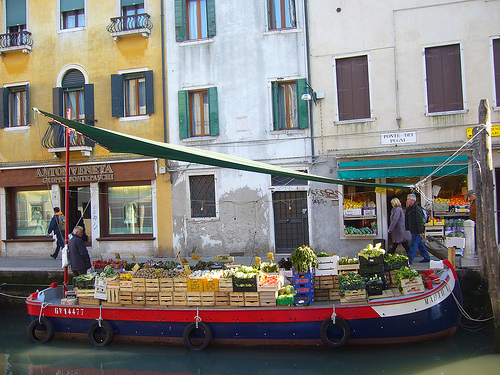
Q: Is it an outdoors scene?
A: Yes, it is outdoors.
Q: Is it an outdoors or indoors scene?
A: It is outdoors.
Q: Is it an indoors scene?
A: No, it is outdoors.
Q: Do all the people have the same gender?
A: No, they are both male and female.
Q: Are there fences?
A: No, there are no fences.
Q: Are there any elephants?
A: No, there are no elephants.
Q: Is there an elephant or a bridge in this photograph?
A: No, there are no elephants or bridges.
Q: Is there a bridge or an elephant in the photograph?
A: No, there are no elephants or bridges.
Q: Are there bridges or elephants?
A: No, there are no elephants or bridges.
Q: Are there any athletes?
A: No, there are no athletes.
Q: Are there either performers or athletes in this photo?
A: No, there are no athletes or performers.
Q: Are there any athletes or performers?
A: No, there are no athletes or performers.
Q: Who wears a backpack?
A: The man wears a backpack.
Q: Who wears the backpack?
A: The man wears a backpack.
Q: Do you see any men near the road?
A: Yes, there is a man near the road.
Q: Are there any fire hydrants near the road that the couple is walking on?
A: No, there is a man near the road.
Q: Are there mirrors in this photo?
A: No, there are no mirrors.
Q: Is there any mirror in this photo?
A: No, there are no mirrors.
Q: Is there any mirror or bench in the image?
A: No, there are no mirrors or benches.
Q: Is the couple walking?
A: Yes, the couple is walking.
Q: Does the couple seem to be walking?
A: Yes, the couple is walking.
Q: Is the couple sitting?
A: No, the couple is walking.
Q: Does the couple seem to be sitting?
A: No, the couple is walking.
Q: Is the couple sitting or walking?
A: The couple is walking.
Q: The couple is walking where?
A: The couple is walking on the road.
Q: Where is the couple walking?
A: The couple is walking on the road.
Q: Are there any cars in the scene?
A: No, there are no cars.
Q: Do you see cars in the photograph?
A: No, there are no cars.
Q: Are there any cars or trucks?
A: No, there are no cars or trucks.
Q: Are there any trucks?
A: No, there are no trucks.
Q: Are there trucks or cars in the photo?
A: No, there are no trucks or cars.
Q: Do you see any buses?
A: No, there are no buses.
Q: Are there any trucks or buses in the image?
A: No, there are no buses or trucks.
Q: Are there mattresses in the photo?
A: No, there are no mattresses.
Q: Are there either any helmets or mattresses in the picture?
A: No, there are no mattresses or helmets.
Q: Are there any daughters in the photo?
A: No, there are no daughters.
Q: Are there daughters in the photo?
A: No, there are no daughters.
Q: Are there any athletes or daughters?
A: No, there are no daughters or athletes.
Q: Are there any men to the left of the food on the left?
A: Yes, there is a man to the left of the food.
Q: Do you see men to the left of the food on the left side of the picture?
A: Yes, there is a man to the left of the food.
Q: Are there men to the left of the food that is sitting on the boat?
A: Yes, there is a man to the left of the food.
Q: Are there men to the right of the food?
A: No, the man is to the left of the food.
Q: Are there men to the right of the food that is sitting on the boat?
A: No, the man is to the left of the food.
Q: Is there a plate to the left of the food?
A: No, there is a man to the left of the food.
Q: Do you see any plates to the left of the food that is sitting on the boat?
A: No, there is a man to the left of the food.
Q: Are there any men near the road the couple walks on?
A: Yes, there is a man near the road.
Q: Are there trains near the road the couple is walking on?
A: No, there is a man near the road.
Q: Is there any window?
A: Yes, there is a window.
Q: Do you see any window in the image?
A: Yes, there is a window.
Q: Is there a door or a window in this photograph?
A: Yes, there is a window.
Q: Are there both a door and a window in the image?
A: Yes, there are both a window and a door.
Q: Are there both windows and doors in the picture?
A: Yes, there are both a window and a door.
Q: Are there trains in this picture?
A: No, there are no trains.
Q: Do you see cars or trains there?
A: No, there are no trains or cars.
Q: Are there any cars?
A: No, there are no cars.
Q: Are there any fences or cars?
A: No, there are no cars or fences.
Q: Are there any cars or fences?
A: No, there are no cars or fences.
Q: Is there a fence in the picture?
A: No, there are no fences.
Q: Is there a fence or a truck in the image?
A: No, there are no fences or trucks.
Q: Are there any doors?
A: Yes, there is a door.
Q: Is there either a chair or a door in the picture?
A: Yes, there is a door.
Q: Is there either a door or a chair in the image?
A: Yes, there is a door.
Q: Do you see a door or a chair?
A: Yes, there is a door.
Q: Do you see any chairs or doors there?
A: Yes, there is a door.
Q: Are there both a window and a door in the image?
A: Yes, there are both a door and a window.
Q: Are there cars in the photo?
A: No, there are no cars.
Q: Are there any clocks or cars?
A: No, there are no cars or clocks.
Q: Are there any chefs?
A: No, there are no chefs.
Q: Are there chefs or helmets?
A: No, there are no chefs or helmets.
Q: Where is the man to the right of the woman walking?
A: The man is walking on the road.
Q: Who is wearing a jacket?
A: The man is wearing a jacket.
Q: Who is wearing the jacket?
A: The man is wearing a jacket.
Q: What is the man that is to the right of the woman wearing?
A: The man is wearing a jacket.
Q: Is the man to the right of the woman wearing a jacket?
A: Yes, the man is wearing a jacket.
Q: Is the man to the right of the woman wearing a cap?
A: No, the man is wearing a jacket.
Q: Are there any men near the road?
A: Yes, there is a man near the road.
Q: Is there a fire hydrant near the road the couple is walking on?
A: No, there is a man near the road.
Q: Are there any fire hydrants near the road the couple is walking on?
A: No, there is a man near the road.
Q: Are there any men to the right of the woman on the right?
A: Yes, there is a man to the right of the woman.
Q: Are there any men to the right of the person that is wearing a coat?
A: Yes, there is a man to the right of the woman.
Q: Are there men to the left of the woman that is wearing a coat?
A: No, the man is to the right of the woman.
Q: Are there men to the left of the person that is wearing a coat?
A: No, the man is to the right of the woman.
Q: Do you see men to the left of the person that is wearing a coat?
A: No, the man is to the right of the woman.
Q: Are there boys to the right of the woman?
A: No, there is a man to the right of the woman.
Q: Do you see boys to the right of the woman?
A: No, there is a man to the right of the woman.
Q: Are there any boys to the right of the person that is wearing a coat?
A: No, there is a man to the right of the woman.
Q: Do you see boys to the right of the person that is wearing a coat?
A: No, there is a man to the right of the woman.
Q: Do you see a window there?
A: Yes, there is a window.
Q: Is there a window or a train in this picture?
A: Yes, there is a window.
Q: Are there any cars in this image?
A: No, there are no cars.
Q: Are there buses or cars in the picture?
A: No, there are no cars or buses.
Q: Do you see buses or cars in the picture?
A: No, there are no cars or buses.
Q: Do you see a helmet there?
A: No, there are no helmets.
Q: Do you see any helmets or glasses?
A: No, there are no helmets or glasses.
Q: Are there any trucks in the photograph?
A: No, there are no trucks.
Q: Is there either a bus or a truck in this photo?
A: No, there are no trucks or buses.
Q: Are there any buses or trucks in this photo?
A: No, there are no trucks or buses.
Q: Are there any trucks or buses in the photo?
A: No, there are no trucks or buses.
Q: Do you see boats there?
A: Yes, there is a boat.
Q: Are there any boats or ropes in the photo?
A: Yes, there is a boat.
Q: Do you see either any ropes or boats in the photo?
A: Yes, there is a boat.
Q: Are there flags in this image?
A: No, there are no flags.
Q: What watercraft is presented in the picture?
A: The watercraft is a boat.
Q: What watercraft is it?
A: The watercraft is a boat.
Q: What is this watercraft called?
A: This is a boat.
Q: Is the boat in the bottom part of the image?
A: Yes, the boat is in the bottom of the image.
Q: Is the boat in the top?
A: No, the boat is in the bottom of the image.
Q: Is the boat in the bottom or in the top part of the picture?
A: The boat is in the bottom of the image.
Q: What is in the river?
A: The boat is in the river.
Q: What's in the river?
A: The boat is in the river.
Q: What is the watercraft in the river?
A: The watercraft is a boat.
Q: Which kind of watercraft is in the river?
A: The watercraft is a boat.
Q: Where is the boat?
A: The boat is in the river.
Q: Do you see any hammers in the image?
A: No, there are no hammers.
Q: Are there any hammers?
A: No, there are no hammers.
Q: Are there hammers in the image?
A: No, there are no hammers.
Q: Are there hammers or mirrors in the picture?
A: No, there are no hammers or mirrors.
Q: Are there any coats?
A: Yes, there is a coat.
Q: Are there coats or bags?
A: Yes, there is a coat.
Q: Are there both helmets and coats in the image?
A: No, there is a coat but no helmets.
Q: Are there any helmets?
A: No, there are no helmets.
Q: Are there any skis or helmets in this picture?
A: No, there are no helmets or skis.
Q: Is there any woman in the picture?
A: Yes, there is a woman.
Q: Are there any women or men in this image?
A: Yes, there is a woman.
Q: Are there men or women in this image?
A: Yes, there is a woman.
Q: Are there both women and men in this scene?
A: Yes, there are both a woman and a man.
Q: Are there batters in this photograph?
A: No, there are no batters.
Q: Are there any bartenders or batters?
A: No, there are no batters or bartenders.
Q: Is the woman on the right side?
A: Yes, the woman is on the right of the image.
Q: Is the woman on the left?
A: No, the woman is on the right of the image.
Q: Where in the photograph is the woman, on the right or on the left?
A: The woman is on the right of the image.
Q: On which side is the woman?
A: The woman is on the right of the image.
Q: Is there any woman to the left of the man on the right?
A: Yes, there is a woman to the left of the man.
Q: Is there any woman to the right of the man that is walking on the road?
A: No, the woman is to the left of the man.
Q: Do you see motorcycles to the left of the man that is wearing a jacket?
A: No, there is a woman to the left of the man.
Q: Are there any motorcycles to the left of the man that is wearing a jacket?
A: No, there is a woman to the left of the man.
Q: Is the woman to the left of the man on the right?
A: Yes, the woman is to the left of the man.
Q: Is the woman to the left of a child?
A: No, the woman is to the left of the man.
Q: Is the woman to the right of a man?
A: No, the woman is to the left of a man.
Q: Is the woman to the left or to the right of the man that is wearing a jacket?
A: The woman is to the left of the man.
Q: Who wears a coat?
A: The woman wears a coat.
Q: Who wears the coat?
A: The woman wears a coat.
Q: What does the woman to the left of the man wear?
A: The woman wears a coat.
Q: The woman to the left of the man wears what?
A: The woman wears a coat.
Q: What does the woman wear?
A: The woman wears a coat.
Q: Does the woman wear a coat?
A: Yes, the woman wears a coat.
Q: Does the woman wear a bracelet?
A: No, the woman wears a coat.